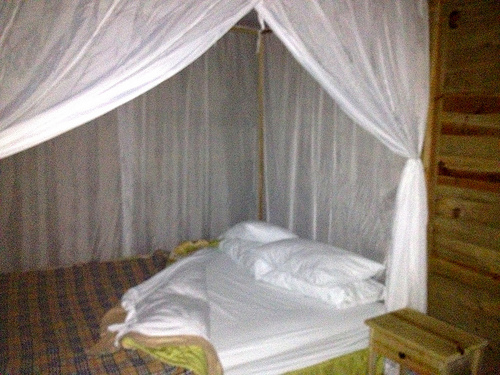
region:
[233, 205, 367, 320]
Pillows on a bed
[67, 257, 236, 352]
Blanket on a bed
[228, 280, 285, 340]
white sheet on a bed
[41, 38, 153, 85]
Curtains over a bed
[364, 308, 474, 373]
Nightstand next to the bed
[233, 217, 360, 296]
Bed with pillows on it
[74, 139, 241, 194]
Bug net over the bed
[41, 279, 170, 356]
Blanket on the bed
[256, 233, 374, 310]
bed with white pillows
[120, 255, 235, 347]
blanket pulled back over bed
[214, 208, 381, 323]
four white pillows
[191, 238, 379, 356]
white sheets on bed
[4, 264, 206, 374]
an orange and black blanket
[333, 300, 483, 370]
a wood table by bed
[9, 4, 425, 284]
white curtains around bed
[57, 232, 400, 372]
a partially made bed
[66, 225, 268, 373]
a turned down cover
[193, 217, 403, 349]
crisp clean white sheets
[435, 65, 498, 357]
a wooden wall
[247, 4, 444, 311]
a curtain tied to the side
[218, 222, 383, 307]
two stacks of pillows on the bed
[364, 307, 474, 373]
wood table next to bed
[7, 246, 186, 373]
plaid blanket on the bed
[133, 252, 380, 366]
white sheets on the bed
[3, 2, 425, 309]
curtains hanging around bed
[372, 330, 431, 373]
drawer of bedside table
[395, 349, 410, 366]
black knob on bedside table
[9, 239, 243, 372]
turned down covers on the bed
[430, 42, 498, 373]
wood wall next to bed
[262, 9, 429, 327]
tied back curtain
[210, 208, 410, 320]
two beautful white pillows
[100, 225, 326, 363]
a beautiful white bed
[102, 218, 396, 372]
a beautiful pillows and bed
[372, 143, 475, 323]
a buttom part of the cloth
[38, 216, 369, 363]
a nice combo of bed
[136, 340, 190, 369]
a small green object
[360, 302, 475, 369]
a small wooden table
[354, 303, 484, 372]
a wooden table placed near to bed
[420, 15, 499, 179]
a nice art on side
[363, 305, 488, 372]
a brown nightstand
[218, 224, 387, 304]
three pillows on a bed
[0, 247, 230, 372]
blanket on the bed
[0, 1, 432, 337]
curtains haniging around the bed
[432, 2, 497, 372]
wooden wall in the bedroom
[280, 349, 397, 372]
bedframe made of wood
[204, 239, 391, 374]
sheet on the bed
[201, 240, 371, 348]
white sheet on a twin bed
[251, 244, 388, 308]
two pillows stacked on the bed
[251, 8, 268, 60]
A tie to hold curtains arount the bed